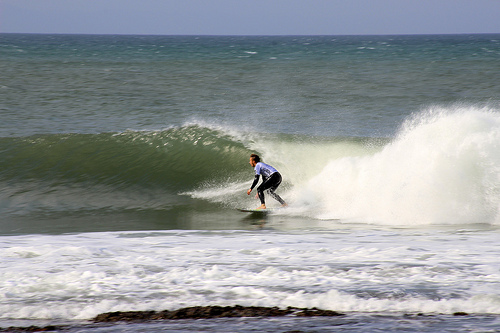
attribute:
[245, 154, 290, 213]
surfer — surfing, bare-footed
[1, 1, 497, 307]
ocean — waterly, water, foamy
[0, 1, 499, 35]
sky — blue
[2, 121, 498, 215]
wave — rolling, crashing, splashing, spashing, white, behind, foamy, breaking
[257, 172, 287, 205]
pants — black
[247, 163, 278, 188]
shirt — blue, purple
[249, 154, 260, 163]
hair — black